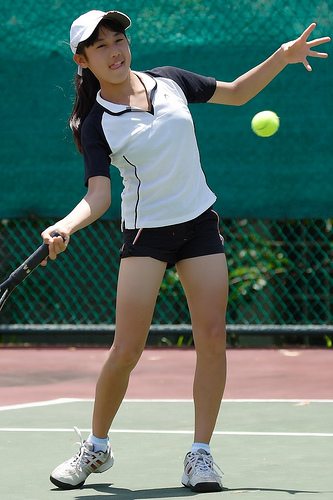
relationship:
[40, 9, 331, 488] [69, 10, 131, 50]
girl wearing hat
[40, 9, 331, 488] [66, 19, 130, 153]
girl has hair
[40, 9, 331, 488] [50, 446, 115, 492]
girl wearing shoe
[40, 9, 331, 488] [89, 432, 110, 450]
girl wearing sock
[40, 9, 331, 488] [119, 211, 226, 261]
girl wearing shorts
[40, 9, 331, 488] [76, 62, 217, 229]
girl wearing shirt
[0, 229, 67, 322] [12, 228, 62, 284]
racket has grip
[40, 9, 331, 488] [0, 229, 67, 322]
girl swinging racket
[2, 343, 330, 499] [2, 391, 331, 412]
tennis court has line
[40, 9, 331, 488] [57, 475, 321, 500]
girl has shadow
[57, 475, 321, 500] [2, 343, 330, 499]
shadow across tennis court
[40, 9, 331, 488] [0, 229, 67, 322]
girl holding racket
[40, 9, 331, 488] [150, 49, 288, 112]
girl has arm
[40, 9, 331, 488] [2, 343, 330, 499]
girl standing on tennis court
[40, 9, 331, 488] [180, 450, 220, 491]
girl wearing shoe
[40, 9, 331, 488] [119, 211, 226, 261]
girl has shorts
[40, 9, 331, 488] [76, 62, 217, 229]
girl has shirt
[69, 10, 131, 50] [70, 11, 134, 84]
hat on top of head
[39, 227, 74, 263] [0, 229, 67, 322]
hand holds racket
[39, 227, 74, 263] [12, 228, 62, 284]
hand holds grip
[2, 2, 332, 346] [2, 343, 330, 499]
fence running behind tennis court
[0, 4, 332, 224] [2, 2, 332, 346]
net over fence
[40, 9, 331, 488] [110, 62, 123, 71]
girl has tongue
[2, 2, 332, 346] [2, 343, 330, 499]
fence around tennis court